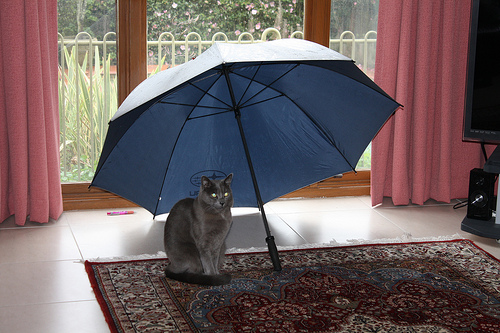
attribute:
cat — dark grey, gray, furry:
[163, 174, 233, 286]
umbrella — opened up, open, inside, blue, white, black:
[87, 38, 403, 272]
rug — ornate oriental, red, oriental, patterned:
[85, 234, 499, 332]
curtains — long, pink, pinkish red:
[1, 0, 65, 224]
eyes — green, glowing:
[211, 191, 229, 198]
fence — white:
[56, 28, 378, 82]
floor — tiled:
[0, 197, 499, 332]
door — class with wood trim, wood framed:
[119, 0, 330, 104]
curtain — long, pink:
[370, 0, 500, 207]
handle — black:
[264, 235, 283, 271]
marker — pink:
[107, 210, 137, 215]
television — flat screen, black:
[461, 0, 499, 144]